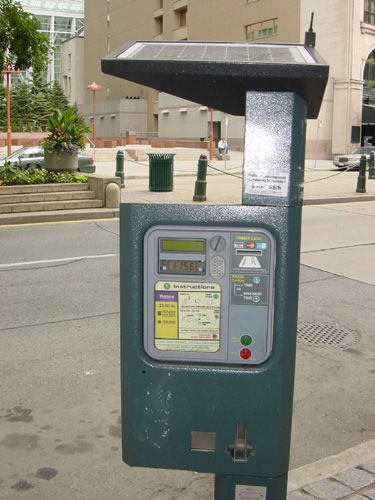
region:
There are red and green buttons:
[239, 320, 250, 370]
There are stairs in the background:
[0, 164, 101, 241]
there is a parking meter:
[103, 177, 321, 425]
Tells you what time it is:
[157, 249, 204, 282]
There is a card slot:
[225, 225, 265, 288]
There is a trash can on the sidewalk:
[141, 148, 187, 195]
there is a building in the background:
[59, 1, 298, 146]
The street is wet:
[9, 386, 81, 497]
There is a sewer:
[282, 311, 365, 366]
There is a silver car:
[333, 137, 366, 182]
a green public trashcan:
[144, 148, 179, 197]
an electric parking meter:
[115, 197, 296, 483]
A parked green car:
[0, 139, 100, 180]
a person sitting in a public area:
[216, 131, 232, 166]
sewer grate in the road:
[294, 304, 361, 355]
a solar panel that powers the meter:
[95, 30, 350, 119]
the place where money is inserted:
[228, 231, 273, 308]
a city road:
[1, 221, 372, 466]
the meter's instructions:
[153, 277, 224, 355]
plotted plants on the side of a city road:
[0, 106, 105, 187]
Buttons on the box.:
[230, 329, 270, 370]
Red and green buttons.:
[233, 331, 266, 372]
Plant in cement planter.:
[25, 83, 102, 179]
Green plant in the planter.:
[38, 90, 109, 176]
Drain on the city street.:
[292, 313, 357, 359]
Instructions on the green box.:
[161, 281, 224, 356]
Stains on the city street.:
[12, 405, 72, 441]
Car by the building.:
[336, 141, 374, 169]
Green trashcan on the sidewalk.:
[145, 145, 191, 211]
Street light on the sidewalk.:
[85, 68, 116, 158]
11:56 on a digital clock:
[154, 259, 207, 276]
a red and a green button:
[227, 328, 267, 367]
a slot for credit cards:
[230, 234, 271, 277]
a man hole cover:
[293, 315, 356, 350]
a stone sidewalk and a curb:
[289, 435, 374, 498]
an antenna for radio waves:
[285, 4, 334, 59]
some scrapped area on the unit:
[134, 366, 181, 453]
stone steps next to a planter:
[0, 160, 86, 229]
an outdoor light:
[85, 74, 101, 151]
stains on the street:
[0, 388, 121, 498]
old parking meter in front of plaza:
[60, 27, 330, 481]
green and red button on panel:
[228, 317, 261, 362]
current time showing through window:
[154, 249, 205, 275]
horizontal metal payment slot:
[225, 232, 265, 268]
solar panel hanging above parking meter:
[90, 20, 330, 207]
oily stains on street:
[5, 399, 110, 484]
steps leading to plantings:
[2, 158, 98, 221]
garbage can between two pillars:
[108, 141, 216, 193]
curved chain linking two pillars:
[190, 153, 370, 179]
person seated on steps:
[203, 120, 234, 172]